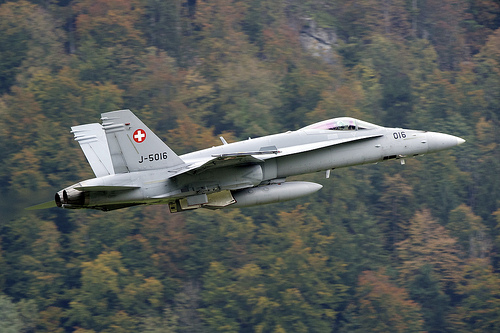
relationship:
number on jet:
[135, 151, 176, 163] [23, 106, 481, 229]